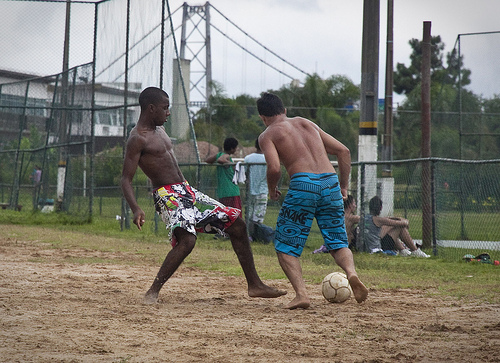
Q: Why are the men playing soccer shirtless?
A: Hot.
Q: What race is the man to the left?
A: Black.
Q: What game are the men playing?
A: Soccer.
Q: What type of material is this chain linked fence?
A: Metal.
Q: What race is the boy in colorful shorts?
A: African.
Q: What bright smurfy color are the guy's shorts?
A: Blue.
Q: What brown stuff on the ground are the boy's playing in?
A: Dirt.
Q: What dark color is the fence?
A: Black.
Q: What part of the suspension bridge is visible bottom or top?
A: Top.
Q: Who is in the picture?
A: Two men.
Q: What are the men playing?
A: Soccer.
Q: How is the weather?
A: Overcast.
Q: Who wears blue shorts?
A: The white boy.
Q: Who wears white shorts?
A: Black boy.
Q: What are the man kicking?
A: Soccer ball.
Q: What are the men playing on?
A: Dirt.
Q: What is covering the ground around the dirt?
A: Grass.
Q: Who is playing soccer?
A: Men.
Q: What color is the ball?
A: White.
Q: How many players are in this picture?
A: Two.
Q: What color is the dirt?
A: Brown.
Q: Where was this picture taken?
A: At a park.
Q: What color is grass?
A: Green.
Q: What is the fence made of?
A: Metal.